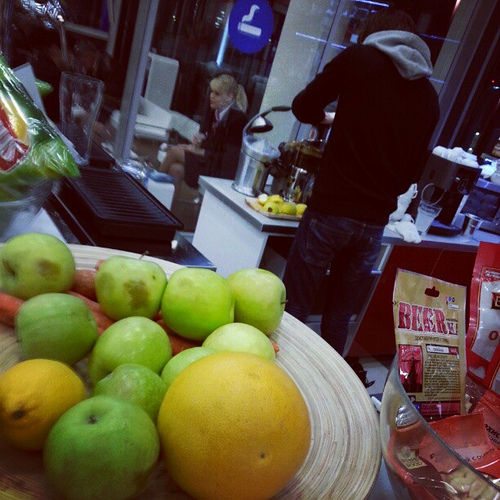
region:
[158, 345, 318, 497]
orange on a big plate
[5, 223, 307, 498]
green apples on a big plate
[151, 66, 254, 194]
blonde woman is sit near a wall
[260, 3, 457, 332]
man is wearing a sweatshirt with hood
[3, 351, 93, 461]
a yellow lemon among apples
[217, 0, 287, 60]
a blue sign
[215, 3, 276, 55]
sign allowing people to smoke in the room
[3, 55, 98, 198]
plastic bags with fruits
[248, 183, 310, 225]
lemons cut in half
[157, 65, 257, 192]
a woman with crossed legs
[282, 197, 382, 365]
man's jeans are blue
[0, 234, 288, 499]
ten apples are green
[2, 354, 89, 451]
lemon is yellow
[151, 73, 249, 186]
woman is sitting down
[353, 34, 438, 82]
man has a hoodie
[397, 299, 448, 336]
letters on bag are red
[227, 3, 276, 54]
sign is a blue circle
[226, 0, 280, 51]
cigarette is on blue sign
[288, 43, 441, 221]
the long sleeve shirt is black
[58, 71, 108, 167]
clear glass is empty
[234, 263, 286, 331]
a crispy green apple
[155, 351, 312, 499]
a big orange grapefruit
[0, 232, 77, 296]
a bruised green apple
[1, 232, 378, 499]
a platter full of fruit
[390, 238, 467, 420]
a package of snack food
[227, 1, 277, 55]
a cigarette smoking sign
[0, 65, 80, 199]
Lay's potato chips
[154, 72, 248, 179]
a woman with her legs crossed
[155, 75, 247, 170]
a blonde woman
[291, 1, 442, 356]
a guy in a hooded sweatshirt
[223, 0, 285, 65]
the sign has a cigarette on it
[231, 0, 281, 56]
the sign is blue & white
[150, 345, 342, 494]
the fruit appears to be a grapefruit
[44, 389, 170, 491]
the apple is green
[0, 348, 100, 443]
the lemon is yellow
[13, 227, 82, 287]
the apple has a bruise on it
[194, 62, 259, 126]
the lady is wearing her hair in a pony tail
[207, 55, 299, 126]
the lady has blonde hair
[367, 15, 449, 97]
the person has a grey hoodie on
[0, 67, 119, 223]
a green bag of chips is in the picture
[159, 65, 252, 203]
A woman sitting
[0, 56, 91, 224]
Part of a bag of Lays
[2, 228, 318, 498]
A plate of fruit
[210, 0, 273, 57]
a smoking sign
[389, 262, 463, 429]
A bag of snacks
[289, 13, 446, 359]
A man with his back to the camera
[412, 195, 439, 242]
A glass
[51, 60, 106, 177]
A glass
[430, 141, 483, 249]
A beverage machine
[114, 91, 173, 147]
Part of a bench